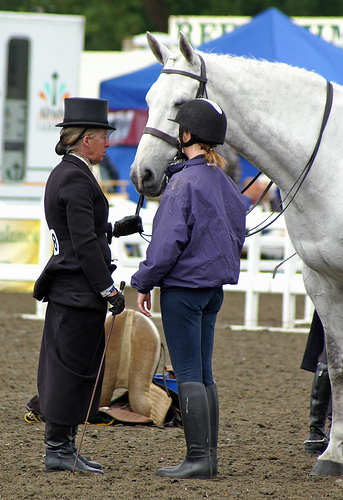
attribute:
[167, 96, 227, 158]
head —  person's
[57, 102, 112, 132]
top hat — black,  woman's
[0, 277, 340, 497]
dirt — brown, soft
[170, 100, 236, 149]
helmet — black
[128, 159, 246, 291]
windbreaker —  purple,  woman's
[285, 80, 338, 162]
harness —  leather 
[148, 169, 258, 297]
jacket —  Purple,  woman's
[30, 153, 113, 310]
black jacket —  Black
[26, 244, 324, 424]
hedges —  white,  wooden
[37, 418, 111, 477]
shoes —  Black 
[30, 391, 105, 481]
boot —  woman's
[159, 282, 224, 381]
blue jeans —  Blue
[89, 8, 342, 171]
tent — blue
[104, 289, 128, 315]
glove — black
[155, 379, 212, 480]
boot —  black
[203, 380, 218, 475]
boot —  black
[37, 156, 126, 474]
garment — black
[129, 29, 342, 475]
horse —  white, white, large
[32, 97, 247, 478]
women — standing by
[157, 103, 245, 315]
equiestrian — standing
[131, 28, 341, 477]
white horse —  white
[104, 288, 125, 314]
gloves —  leather ,  black